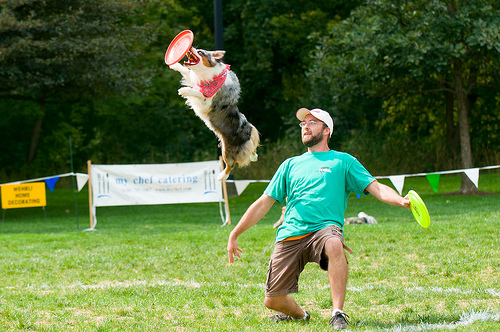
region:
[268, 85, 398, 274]
man playing frisbee on field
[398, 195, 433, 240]
yellow frisbee in man's hand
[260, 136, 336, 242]
green t shirt on man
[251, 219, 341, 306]
brown shorts on man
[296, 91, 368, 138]
white cap on man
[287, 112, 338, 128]
eye glasses on man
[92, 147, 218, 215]
white banner by field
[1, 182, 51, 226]
yellow sign on rope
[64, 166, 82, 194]
white flags on rope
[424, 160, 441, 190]
green flags on rope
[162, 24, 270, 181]
dog jumping to catch frisbee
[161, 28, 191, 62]
red frisbee dog is catching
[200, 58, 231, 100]
red bandana around dog's neck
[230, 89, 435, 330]
man holding green frisbee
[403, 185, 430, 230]
frisbee man is holding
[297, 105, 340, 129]
white hat man is wearing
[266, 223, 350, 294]
brown shorts man is wearing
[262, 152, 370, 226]
green shirt man is wearing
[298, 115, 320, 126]
glasses of man holding frisbee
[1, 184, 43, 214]
yellow sign with black lettering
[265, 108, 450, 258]
a man holding a frisbee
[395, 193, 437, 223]
a green frisbee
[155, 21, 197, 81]
a red frisbee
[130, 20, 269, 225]
a dog up off the ground to catch a frisbee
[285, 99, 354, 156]
a man wearing glasses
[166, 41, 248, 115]
a dog with a red bandanna around its necks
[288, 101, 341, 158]
a man wearing white cap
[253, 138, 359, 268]
a man wearing a green shirt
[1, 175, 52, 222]
a yellow sign with black letters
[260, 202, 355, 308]
a man wearing brown shorts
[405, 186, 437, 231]
green flying disk being held in hand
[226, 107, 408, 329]
man is in a very odd position on the ground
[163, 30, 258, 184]
mans dog catching frisbee high in the air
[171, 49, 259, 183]
dog jumps very high off ground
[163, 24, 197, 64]
red frisbee being caught by dog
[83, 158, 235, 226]
advertisement sign in middle of boundaries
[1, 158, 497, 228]
boundary lines of competition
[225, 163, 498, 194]
colorful flags hanging in the wind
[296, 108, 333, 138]
man is wearing a hat and glasses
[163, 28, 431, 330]
competition contestants performing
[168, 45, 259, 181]
the dog in mid air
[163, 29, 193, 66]
the frisbee in mid air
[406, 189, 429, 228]
the frisbee in the man's hand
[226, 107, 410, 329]
the man behind the dog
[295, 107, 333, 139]
the hat on the man's head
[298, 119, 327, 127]
the glasses on the man's face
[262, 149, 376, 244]
the short sleeved shirt on the man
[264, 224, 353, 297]
the brown shorts on the man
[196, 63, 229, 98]
the fabric wrapped around the dog's neck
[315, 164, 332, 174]
the design on the man's shirt